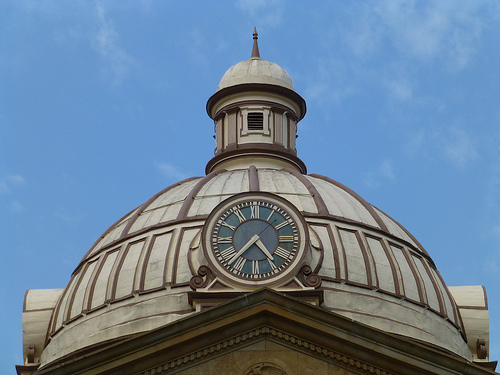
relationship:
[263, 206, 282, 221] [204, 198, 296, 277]
numeral on clock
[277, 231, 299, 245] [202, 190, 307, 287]
numeral on clock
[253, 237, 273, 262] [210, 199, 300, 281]
hour hand on clock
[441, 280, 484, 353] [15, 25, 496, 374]
facade on tower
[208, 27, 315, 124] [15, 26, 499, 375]
top of tower